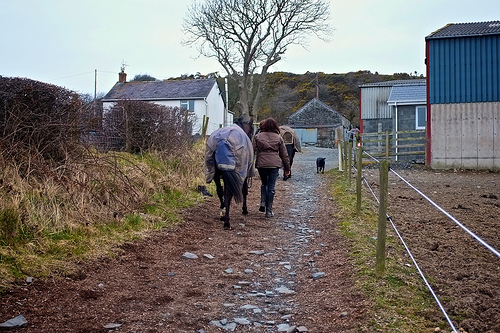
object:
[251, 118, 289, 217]
woman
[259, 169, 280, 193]
blue jeans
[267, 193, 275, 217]
black boots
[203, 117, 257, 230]
horse